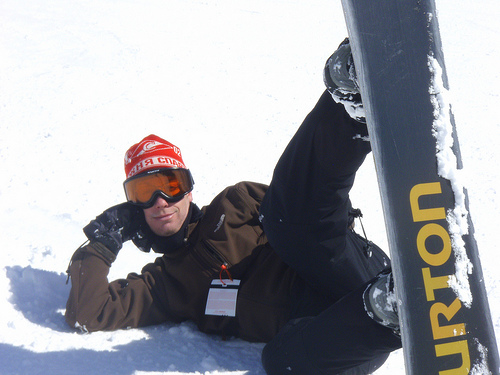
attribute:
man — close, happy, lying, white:
[60, 0, 480, 369]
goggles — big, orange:
[119, 168, 197, 201]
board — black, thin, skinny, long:
[352, 5, 499, 373]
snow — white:
[26, 25, 326, 154]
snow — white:
[74, 32, 256, 82]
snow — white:
[3, 5, 267, 135]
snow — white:
[0, 156, 60, 364]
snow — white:
[12, 13, 254, 94]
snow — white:
[10, 44, 66, 364]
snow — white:
[372, 205, 383, 235]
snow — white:
[4, 335, 240, 370]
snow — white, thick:
[2, 5, 483, 369]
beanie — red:
[119, 134, 187, 172]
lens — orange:
[125, 169, 192, 200]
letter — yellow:
[408, 180, 448, 222]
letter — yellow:
[414, 220, 453, 265]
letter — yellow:
[419, 265, 457, 301]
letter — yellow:
[426, 296, 467, 338]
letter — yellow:
[432, 338, 471, 372]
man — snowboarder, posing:
[66, 36, 402, 373]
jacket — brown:
[62, 180, 297, 338]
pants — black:
[259, 92, 402, 372]